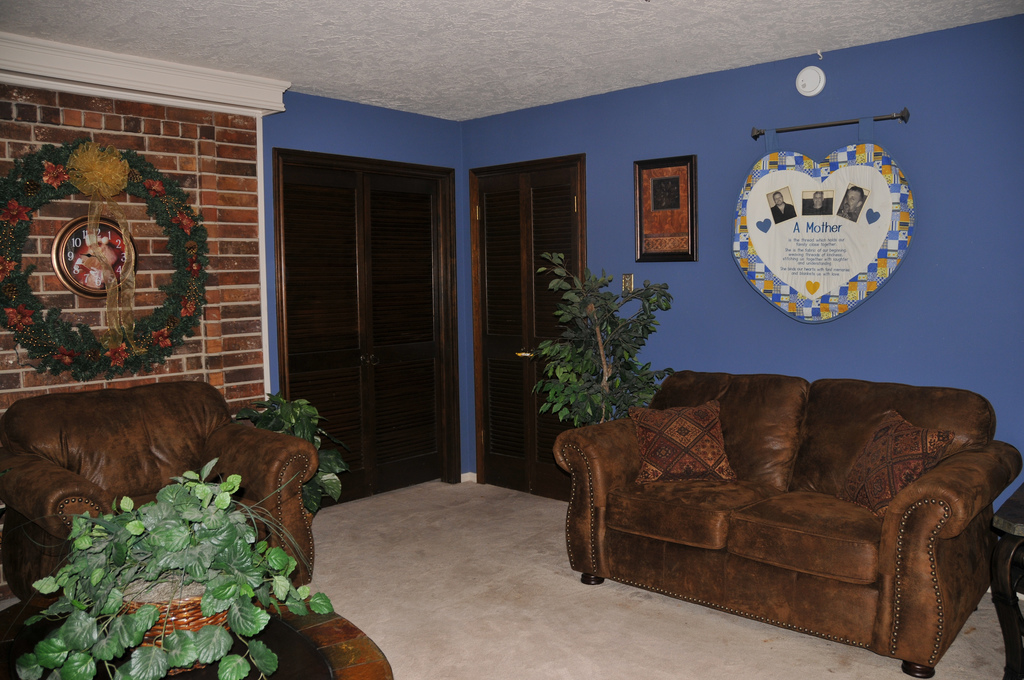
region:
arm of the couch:
[522, 366, 691, 543]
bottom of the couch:
[452, 503, 958, 677]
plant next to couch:
[489, 233, 709, 461]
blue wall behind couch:
[901, 189, 988, 360]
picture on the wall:
[590, 145, 720, 301]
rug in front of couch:
[424, 556, 557, 665]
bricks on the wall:
[6, 158, 262, 386]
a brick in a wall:
[216, 121, 268, 144]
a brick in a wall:
[201, 155, 255, 172]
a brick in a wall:
[204, 182, 249, 195]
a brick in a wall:
[214, 203, 262, 222]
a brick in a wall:
[211, 219, 265, 245]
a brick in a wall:
[221, 262, 261, 275]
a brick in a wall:
[218, 300, 261, 329]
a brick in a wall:
[224, 349, 267, 372]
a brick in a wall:
[225, 373, 270, 393]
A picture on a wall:
[722, 142, 918, 319]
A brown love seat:
[554, 354, 1010, 667]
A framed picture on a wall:
[621, 151, 701, 273]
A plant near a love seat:
[538, 246, 669, 402]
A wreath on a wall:
[4, 151, 214, 361]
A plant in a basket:
[36, 481, 316, 677]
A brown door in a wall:
[488, 156, 574, 489]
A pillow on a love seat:
[634, 404, 739, 480]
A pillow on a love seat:
[861, 417, 939, 494]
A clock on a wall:
[42, 224, 147, 295]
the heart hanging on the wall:
[732, 147, 914, 326]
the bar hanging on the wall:
[748, 109, 913, 142]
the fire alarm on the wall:
[791, 63, 830, 99]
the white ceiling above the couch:
[1, 0, 1023, 121]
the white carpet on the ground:
[298, 474, 1013, 677]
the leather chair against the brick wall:
[1, 370, 318, 596]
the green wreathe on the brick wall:
[2, 135, 217, 382]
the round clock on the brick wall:
[53, 212, 139, 301]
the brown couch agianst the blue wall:
[554, 365, 1023, 678]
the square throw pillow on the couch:
[631, 398, 734, 488]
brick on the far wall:
[191, 150, 265, 182]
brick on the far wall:
[196, 169, 255, 195]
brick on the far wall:
[190, 188, 258, 208]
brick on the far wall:
[198, 220, 260, 239]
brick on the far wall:
[197, 236, 255, 255]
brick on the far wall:
[194, 248, 258, 269]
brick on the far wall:
[200, 264, 262, 284]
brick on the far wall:
[194, 283, 256, 297]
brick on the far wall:
[190, 299, 257, 316]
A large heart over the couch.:
[732, 138, 917, 326]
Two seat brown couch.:
[552, 371, 1020, 678]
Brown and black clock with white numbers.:
[52, 218, 139, 298]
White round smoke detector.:
[793, 63, 825, 98]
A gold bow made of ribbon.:
[62, 139, 130, 346]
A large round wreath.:
[3, 136, 212, 383]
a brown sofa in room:
[524, 351, 997, 677]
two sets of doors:
[269, 136, 596, 516]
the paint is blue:
[923, 79, 1010, 288]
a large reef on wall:
[3, 127, 216, 383]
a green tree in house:
[505, 247, 680, 435]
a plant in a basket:
[0, 435, 355, 677]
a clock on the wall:
[51, 184, 146, 301]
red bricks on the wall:
[202, 143, 248, 260]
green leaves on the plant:
[557, 312, 581, 331]